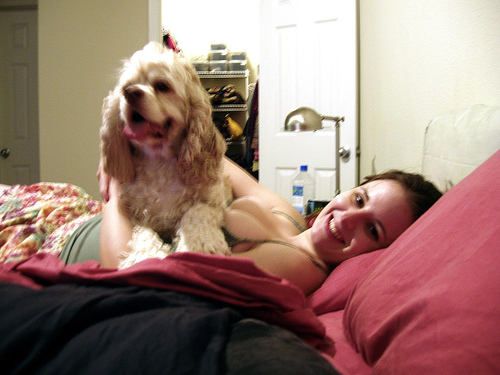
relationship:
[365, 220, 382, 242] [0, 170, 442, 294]
eye on girl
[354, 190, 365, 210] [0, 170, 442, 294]
eye on girl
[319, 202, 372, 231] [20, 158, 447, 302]
nose on girl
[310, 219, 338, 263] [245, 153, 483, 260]
chin on girl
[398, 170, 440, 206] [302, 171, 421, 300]
hair on girl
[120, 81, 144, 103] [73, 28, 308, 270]
nose on dog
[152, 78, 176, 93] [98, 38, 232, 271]
dog eye on dog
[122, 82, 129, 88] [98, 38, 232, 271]
dog eye on dog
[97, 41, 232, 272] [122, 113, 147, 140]
dog has tongue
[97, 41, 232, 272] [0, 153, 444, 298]
dog sitting on girl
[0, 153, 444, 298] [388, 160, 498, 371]
girl lying on bed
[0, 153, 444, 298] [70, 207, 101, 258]
girl wearing tank top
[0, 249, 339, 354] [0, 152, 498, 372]
sheets on bed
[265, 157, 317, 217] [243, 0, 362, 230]
plastic bottle in front of door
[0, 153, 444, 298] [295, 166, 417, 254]
girl has a face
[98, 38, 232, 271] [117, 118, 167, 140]
dog has a tongue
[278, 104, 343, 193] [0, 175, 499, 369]
lamp next to bed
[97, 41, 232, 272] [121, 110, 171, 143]
dog has tongue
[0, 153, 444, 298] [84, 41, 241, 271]
girl playing with dog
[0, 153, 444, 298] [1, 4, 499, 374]
girl in room